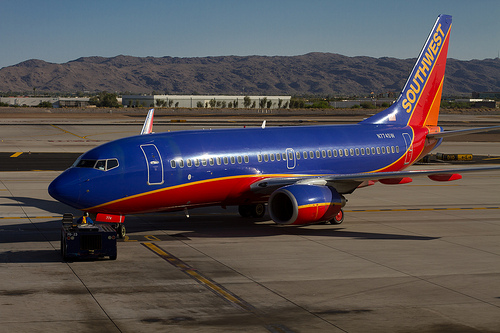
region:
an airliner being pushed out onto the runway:
[27, 22, 486, 273]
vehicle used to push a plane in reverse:
[52, 203, 142, 273]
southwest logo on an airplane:
[375, 7, 466, 143]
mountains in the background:
[10, 21, 486, 133]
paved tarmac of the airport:
[12, 237, 474, 327]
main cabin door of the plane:
[134, 140, 169, 187]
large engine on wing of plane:
[262, 177, 363, 237]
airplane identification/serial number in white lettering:
[371, 125, 401, 143]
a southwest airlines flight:
[25, 7, 490, 267]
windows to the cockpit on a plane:
[72, 150, 127, 180]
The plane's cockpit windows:
[78, 157, 118, 169]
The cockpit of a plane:
[76, 160, 124, 195]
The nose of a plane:
[46, 180, 73, 198]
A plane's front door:
[139, 145, 166, 185]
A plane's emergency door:
[284, 145, 297, 169]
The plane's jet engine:
[267, 189, 297, 226]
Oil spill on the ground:
[245, 313, 277, 328]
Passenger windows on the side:
[309, 149, 346, 156]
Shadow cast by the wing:
[353, 231, 393, 239]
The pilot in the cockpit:
[98, 163, 105, 170]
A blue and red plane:
[45, 11, 452, 234]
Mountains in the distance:
[1, 53, 498, 109]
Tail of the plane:
[371, 10, 455, 130]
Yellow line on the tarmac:
[141, 238, 261, 315]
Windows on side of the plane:
[168, 140, 403, 175]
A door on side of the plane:
[136, 139, 168, 189]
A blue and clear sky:
[1, 0, 498, 61]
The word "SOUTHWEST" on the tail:
[399, 19, 452, 116]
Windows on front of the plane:
[74, 154, 120, 174]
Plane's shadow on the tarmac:
[1, 192, 444, 253]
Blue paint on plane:
[188, 134, 213, 145]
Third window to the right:
[103, 157, 122, 169]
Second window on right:
[92, 158, 109, 171]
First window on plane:
[76, 157, 98, 169]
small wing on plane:
[140, 106, 157, 133]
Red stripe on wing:
[436, 49, 441, 83]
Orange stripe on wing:
[429, 104, 434, 129]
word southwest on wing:
[398, 14, 446, 110]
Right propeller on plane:
[267, 180, 356, 230]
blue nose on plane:
[41, 172, 71, 202]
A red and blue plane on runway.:
[38, 97, 420, 227]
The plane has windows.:
[183, 138, 389, 168]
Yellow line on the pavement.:
[159, 240, 237, 314]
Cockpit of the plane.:
[71, 138, 122, 180]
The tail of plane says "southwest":
[392, 37, 454, 105]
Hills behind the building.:
[86, 38, 376, 111]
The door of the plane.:
[131, 138, 166, 188]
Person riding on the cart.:
[49, 210, 121, 255]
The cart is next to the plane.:
[47, 207, 134, 275]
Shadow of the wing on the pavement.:
[307, 210, 434, 250]